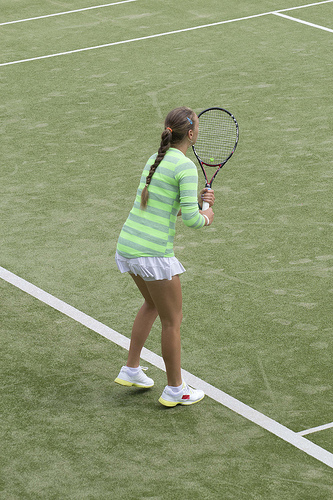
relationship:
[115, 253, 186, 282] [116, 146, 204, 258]
shorts wears shirt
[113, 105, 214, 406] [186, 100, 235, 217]
player holds racket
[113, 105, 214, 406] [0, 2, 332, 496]
player on court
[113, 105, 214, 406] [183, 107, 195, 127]
player wears barrette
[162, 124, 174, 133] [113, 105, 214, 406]
hairband worn by player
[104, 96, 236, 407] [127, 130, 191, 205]
player wears braid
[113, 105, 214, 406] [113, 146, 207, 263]
player wears top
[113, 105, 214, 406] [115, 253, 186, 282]
player wears shorts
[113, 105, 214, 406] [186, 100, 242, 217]
player holds racket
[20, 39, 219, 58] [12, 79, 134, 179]
white line on ground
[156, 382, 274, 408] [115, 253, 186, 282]
shoes on shorts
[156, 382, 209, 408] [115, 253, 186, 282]
shoes on shorts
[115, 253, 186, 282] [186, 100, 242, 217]
shorts holds racket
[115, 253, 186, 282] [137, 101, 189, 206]
shorts has hair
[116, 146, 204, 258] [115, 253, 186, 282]
shirt on shorts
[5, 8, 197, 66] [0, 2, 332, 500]
lines on court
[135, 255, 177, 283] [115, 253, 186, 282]
shorts on shorts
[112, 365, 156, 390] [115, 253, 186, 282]
shoe on shorts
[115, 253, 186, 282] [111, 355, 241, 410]
shorts wearing tennis shoes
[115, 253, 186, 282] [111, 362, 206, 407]
shorts wearing tennis shoes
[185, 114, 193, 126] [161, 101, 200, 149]
hair pin on head